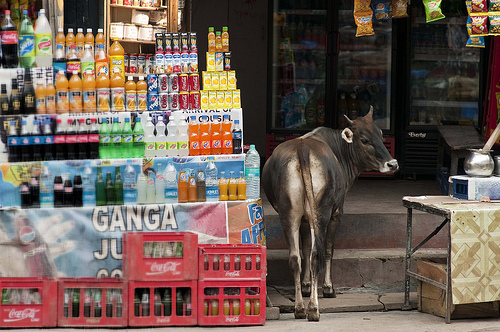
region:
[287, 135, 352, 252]
the tail of a cow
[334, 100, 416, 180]
the head of a cow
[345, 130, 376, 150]
the eye of a cow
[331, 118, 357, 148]
the ear of a cow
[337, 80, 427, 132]
the horns on a cow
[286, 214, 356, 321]
the back legs of a cow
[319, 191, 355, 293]
the front leg of a cow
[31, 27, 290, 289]
a lot of soda near a cow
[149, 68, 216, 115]
a stack of cans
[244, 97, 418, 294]
a cow near some soda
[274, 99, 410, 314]
a cow standing on a sidewalk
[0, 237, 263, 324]
several red plastic soda bins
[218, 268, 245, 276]
white logo on the red bin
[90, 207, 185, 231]
white lettering on a colorful sign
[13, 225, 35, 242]
pepsi logo on the sign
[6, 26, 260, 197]
assorted sodas on the table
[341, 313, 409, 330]
grey concrete surface of the sidewalk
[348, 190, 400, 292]
red and grey concrete of the stairs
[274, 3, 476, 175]
two soda coolers next to a building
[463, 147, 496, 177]
a metal pot on a table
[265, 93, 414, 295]
the cow is brown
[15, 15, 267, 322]
different beverages on display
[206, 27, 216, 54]
A bottle of orange flavored liquid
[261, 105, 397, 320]
A cow next to various drinks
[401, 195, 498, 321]
A table that is holding items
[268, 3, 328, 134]
The window of a beverage refrigerator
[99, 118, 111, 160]
A bottle of lemon lime soda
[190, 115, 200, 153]
A bottle of orange soda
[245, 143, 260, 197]
A bottle of water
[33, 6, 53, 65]
A plastic bottle with a drink inside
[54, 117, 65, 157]
A bottle of cola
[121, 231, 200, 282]
A soda branded crate